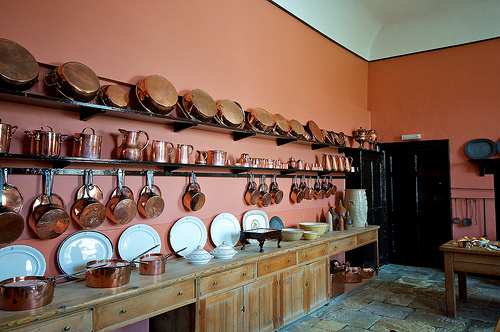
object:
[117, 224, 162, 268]
plate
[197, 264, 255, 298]
drawer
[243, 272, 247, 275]
handle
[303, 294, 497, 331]
floor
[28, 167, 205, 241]
pans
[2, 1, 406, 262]
wall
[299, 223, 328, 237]
bowl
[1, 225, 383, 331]
table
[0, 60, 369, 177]
shelf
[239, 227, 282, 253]
tray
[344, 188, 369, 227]
jug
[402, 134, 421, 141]
fixture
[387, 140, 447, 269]
door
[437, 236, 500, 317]
table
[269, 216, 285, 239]
plate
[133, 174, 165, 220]
pot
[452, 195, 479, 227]
soup ladel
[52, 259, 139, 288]
pots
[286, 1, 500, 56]
ceiling